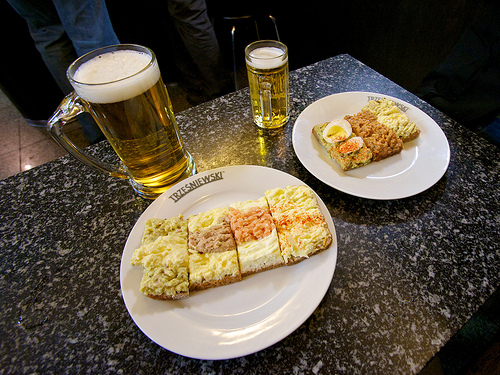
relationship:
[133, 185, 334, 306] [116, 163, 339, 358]
food on plate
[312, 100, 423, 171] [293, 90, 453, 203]
food on plate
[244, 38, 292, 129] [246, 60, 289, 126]
mug has beer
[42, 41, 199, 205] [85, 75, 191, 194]
mug has beer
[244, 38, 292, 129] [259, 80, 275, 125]
mug has handle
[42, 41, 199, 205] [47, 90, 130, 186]
mug has handle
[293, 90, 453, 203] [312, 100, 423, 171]
plate has food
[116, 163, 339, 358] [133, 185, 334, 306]
plate has food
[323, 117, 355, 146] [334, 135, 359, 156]
egg has paprika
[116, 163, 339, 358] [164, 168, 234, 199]
plate has writing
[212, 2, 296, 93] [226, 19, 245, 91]
chair has leg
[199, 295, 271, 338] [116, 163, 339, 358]
part of plate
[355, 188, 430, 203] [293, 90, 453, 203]
edge of plate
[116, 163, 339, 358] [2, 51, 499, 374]
plate on counter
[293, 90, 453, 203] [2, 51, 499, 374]
plate on counter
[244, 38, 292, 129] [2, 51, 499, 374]
mug on counter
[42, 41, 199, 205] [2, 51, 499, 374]
mug on counter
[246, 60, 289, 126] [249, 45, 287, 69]
beer has foam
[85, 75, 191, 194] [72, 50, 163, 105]
beer has foam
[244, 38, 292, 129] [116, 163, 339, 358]
mug beside plate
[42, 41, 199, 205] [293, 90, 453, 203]
mug beside plate